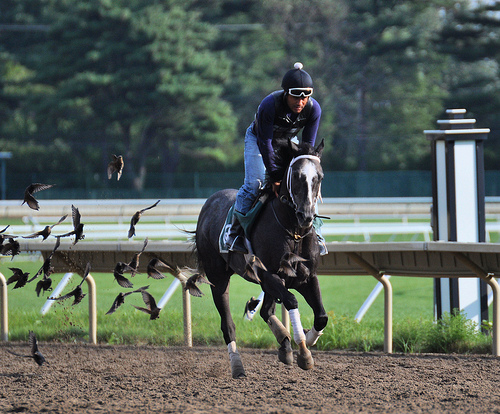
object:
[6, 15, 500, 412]
not seen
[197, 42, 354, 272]
jockey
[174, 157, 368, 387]
horse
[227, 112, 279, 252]
pants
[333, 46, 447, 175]
trees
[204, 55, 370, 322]
man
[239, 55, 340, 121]
helmet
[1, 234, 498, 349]
railing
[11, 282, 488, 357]
grass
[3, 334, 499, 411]
dirt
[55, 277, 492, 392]
course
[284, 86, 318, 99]
goggles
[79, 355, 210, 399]
surfaces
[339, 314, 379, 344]
surfaces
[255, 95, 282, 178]
arm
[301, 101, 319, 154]
arm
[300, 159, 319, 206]
stripe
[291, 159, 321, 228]
face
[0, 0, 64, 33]
leaves